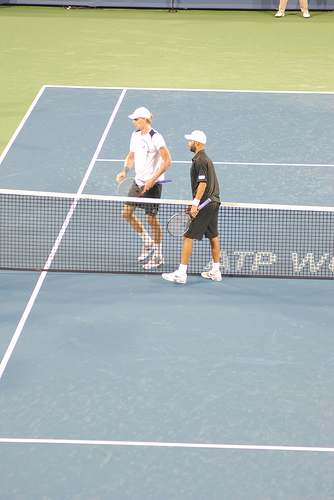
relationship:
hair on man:
[144, 112, 152, 124] [114, 105, 171, 272]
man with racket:
[160, 128, 222, 283] [163, 204, 197, 237]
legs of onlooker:
[275, 0, 310, 9] [264, 0, 320, 22]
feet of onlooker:
[160, 262, 228, 282] [264, 0, 320, 22]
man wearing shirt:
[114, 105, 173, 269] [127, 129, 168, 187]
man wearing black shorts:
[114, 105, 173, 269] [124, 178, 163, 213]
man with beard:
[160, 128, 222, 283] [188, 140, 196, 151]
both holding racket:
[105, 97, 236, 290] [164, 197, 214, 240]